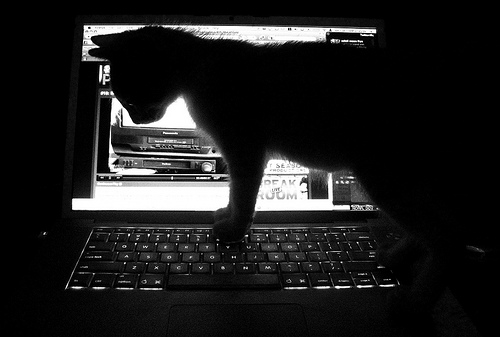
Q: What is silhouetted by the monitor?
A: Cat.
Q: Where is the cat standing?
A: On keyboard.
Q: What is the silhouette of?
A: Cat.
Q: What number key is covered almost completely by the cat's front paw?
A: 7.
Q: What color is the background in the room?
A: Black.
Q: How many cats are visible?
A: One.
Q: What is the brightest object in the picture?
A: Screen.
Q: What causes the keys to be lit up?
A: Backlight.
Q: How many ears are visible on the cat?
A: Two.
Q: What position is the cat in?
A: Standing.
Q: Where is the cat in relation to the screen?
A: Front.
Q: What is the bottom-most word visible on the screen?
A: Room.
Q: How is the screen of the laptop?
A: Bright and illuminated.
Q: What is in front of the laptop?
A: Cat.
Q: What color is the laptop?
A: Black.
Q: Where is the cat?
A: In front of laptop.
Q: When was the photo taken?
A: Night.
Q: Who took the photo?
A: Owner of laptop.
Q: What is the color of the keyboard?
A: Black.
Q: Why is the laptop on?
A: Being used.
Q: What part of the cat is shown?
A: Side.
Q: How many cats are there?
A: One.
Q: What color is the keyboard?
A: Black.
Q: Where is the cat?
A: On the keyboard.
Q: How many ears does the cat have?
A: Two.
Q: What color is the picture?
A: Black and white.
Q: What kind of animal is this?
A: Cat.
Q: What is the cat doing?
A: Using the keyboard.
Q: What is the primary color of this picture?
A: Black.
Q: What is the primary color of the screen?
A: White.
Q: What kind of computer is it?
A: Laptop.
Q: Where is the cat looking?
A: Down.